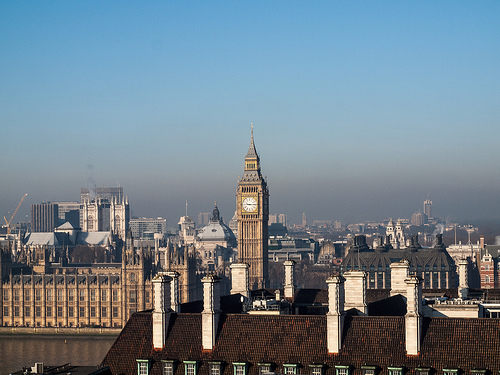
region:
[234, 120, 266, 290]
old tall clock tower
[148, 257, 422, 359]
several white chimneys on one roof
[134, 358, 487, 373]
line of windows on a building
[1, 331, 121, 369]
waterway in a city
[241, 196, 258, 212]
round white clock atop a clock tower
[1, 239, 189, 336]
old brown brick building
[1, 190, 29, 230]
a large crane in the city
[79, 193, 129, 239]
two building side by side with white peaks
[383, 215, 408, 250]
two identical buildings side by side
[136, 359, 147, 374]
window on the building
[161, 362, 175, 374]
window on the building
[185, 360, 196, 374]
window on the building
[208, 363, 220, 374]
window on the building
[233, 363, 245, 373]
window on the building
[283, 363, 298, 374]
window on the building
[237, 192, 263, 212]
clock on the tower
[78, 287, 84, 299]
window on the building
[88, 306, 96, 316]
window on the building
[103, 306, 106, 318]
window on the building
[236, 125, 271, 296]
a tall clock tower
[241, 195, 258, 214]
the white face of a clock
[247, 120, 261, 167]
the steeple of the tower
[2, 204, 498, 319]
the tops of buildings across a city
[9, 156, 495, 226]
a line of smog above the city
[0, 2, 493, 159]
a cloudless light blue sky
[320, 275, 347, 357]
a white pillar on the roof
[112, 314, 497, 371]
a dark brown roof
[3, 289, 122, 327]
windows on a tan building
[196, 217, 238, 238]
the rounded top of a building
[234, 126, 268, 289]
Tower of Big Ben in London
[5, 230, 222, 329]
Parliament government building in London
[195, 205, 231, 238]
Green dome of church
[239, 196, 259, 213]
Clock face on tower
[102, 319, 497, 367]
Slanted roof on building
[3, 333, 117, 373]
Thames river in London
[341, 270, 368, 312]
Brick chimney on building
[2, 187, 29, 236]
Metal construction crane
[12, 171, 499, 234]
Haze in lower part of sky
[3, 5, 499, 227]
Clear blue sky with haze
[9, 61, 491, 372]
this is the city of London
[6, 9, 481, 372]
this is a view of London, England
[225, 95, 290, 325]
this is Big Ben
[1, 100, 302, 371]
this is the Palace of Westminster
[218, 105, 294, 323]
this is a clock tower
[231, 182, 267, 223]
the clock is a circle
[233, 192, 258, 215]
the clock is round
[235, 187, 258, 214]
the clock is white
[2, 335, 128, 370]
this is a river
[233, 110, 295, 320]
a tall clock tower